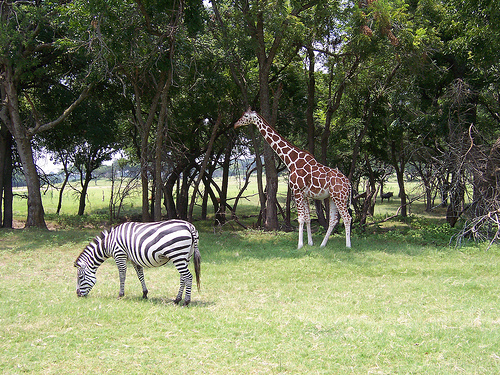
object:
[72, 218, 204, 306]
zebra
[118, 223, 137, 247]
stripes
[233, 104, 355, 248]
giraffe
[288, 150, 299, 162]
spot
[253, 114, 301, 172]
neck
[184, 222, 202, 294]
tail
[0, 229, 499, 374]
grass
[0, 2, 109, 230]
trees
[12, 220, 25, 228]
dirt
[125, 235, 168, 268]
belly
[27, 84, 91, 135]
branch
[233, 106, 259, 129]
head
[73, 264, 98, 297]
head